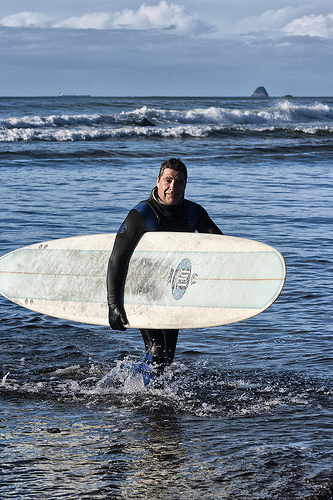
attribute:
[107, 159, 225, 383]
man — looking, here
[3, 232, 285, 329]
surfboard — blue, white, here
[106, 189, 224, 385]
suit — here, blue, black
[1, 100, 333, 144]
wave — here, white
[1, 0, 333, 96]
sky — here, cloudy, white, dark, blue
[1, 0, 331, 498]
photo — here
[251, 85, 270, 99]
island — here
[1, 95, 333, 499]
ocean — blue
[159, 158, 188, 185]
hair — brown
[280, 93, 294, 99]
ship — here